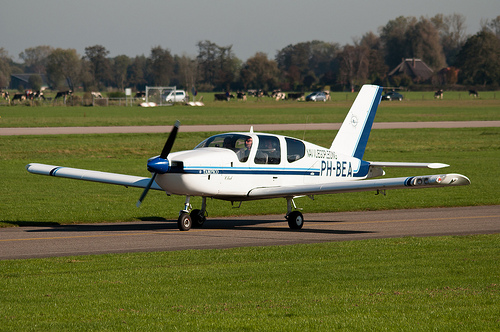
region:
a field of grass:
[179, 262, 385, 321]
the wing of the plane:
[24, 155, 136, 189]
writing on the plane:
[313, 157, 350, 179]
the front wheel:
[175, 214, 193, 231]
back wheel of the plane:
[286, 210, 315, 232]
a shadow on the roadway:
[66, 219, 141, 233]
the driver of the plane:
[232, 135, 250, 153]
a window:
[260, 137, 280, 163]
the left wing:
[369, 168, 464, 193]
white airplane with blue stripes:
[21, 79, 480, 246]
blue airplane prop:
[130, 118, 185, 210]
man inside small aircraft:
[227, 127, 259, 172]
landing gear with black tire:
[281, 192, 319, 239]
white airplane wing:
[18, 149, 150, 195]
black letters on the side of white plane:
[312, 154, 359, 179]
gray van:
[157, 80, 196, 109]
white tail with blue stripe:
[326, 70, 387, 163]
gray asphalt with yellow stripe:
[55, 215, 171, 269]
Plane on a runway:
[25, 80, 498, 252]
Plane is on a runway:
[11, 78, 473, 232]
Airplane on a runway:
[23, 82, 473, 237]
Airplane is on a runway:
[24, 77, 476, 238]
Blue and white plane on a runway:
[24, 77, 476, 235]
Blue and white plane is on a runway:
[25, 77, 472, 242]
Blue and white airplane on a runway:
[20, 80, 472, 235]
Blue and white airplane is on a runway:
[21, 74, 478, 241]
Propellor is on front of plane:
[129, 115, 192, 214]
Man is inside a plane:
[238, 132, 261, 162]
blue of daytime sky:
[3, 2, 496, 62]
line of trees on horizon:
[2, 14, 496, 89]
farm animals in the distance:
[6, 85, 284, 106]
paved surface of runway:
[2, 202, 498, 257]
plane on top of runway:
[27, 83, 472, 229]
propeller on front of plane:
[137, 119, 182, 206]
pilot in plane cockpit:
[202, 131, 286, 166]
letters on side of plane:
[319, 160, 353, 177]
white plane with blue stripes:
[156, 130, 369, 195]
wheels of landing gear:
[177, 206, 305, 230]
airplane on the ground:
[23, 97, 448, 250]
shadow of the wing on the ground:
[234, 217, 349, 240]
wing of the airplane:
[296, 155, 471, 206]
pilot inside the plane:
[235, 131, 258, 166]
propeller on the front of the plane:
[114, 103, 194, 226]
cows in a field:
[11, 82, 96, 98]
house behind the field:
[388, 50, 435, 95]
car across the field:
[162, 85, 189, 105]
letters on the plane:
[315, 156, 352, 182]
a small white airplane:
[22, 76, 470, 229]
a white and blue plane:
[25, 78, 472, 232]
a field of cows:
[7, 74, 483, 101]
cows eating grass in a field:
[1, 81, 487, 106]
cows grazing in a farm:
[0, 82, 499, 104]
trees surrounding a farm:
[3, 12, 499, 88]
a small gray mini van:
[161, 86, 187, 103]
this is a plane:
[94, 68, 499, 323]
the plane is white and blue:
[101, 101, 444, 243]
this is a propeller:
[122, 105, 219, 241]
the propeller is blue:
[124, 128, 198, 211]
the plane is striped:
[193, 133, 275, 190]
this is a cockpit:
[137, 70, 340, 217]